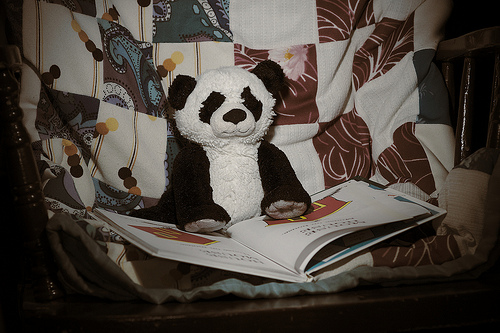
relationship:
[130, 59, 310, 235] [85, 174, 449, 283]
teddy bear reading a book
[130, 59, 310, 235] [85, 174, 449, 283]
teddy bear has a book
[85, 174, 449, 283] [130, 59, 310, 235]
book in front of teddy bear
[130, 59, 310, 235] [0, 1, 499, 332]
teddy bear in a chair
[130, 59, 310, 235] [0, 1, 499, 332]
teddy bear in chair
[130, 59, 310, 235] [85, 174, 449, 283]
teddy bear under book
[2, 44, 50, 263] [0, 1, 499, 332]
arm of chair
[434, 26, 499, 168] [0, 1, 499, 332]
arm of chair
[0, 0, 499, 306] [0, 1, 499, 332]
quilt on chair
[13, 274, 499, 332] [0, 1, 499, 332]
seat of chair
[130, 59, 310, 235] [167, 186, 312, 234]
teddy bear has hands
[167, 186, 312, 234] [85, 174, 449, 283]
hands on book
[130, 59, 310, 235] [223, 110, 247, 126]
teddy bear has a nose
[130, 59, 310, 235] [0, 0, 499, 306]
teddy bear sitting on quilt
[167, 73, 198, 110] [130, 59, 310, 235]
ear on teddy bear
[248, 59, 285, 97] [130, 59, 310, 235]
ear on teddy bear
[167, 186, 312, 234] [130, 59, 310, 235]
hands on teddy bear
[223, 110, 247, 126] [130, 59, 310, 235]
nose on teddy bear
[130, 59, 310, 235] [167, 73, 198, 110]
teddy bear has a ear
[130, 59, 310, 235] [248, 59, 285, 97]
teddy bear has a ear